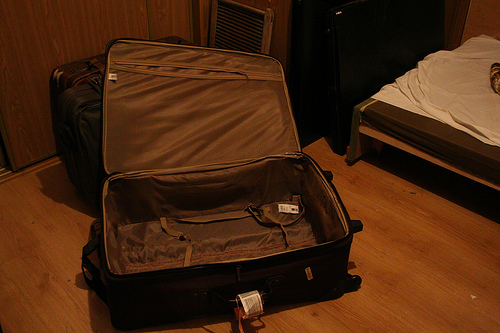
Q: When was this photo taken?
A: At night.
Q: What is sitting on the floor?
A: Suitcase.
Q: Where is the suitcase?
A: On the floor.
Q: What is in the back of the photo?
A: A bed.